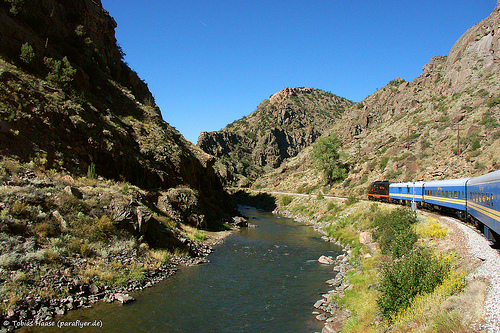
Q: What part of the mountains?
A: The rocky bottom.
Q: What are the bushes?
A: Green.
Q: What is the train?
A: Moving.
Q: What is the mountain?
A: Steep.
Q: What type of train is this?
A: Passenger.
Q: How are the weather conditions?
A: Clear.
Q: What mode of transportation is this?
A: Train.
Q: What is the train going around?
A: Bend.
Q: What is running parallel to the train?
A: River.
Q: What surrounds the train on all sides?
A: Rocky hills.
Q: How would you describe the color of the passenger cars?
A: Blue, and white.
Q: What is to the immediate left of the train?
A: Embankment.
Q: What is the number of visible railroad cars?
A: 4.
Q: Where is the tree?
A: Side of mountain.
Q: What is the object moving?
A: Train.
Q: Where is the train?
A: Tracks.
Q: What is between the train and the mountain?
A: River.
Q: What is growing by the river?
A: Bushes.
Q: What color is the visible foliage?
A: Yellow and green.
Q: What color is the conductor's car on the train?
A: Black and orange.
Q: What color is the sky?
A: Blue.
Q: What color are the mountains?
A: Brown.